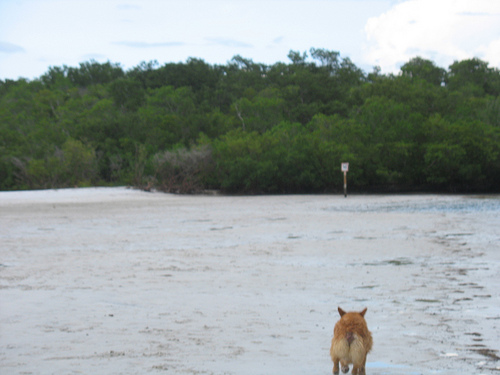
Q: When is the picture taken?
A: Daytime.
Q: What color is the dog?
A: Brown.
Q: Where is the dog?
A: In the sand.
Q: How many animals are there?
A: 1.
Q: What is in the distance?
A: A sign.